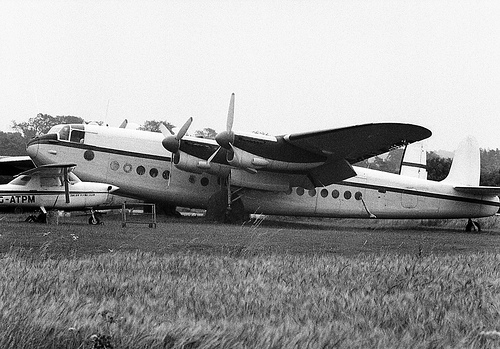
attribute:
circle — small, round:
[136, 163, 146, 181]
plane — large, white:
[24, 110, 499, 231]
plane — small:
[5, 164, 122, 223]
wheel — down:
[461, 215, 487, 235]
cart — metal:
[110, 194, 177, 238]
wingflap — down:
[308, 154, 360, 200]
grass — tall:
[231, 197, 287, 266]